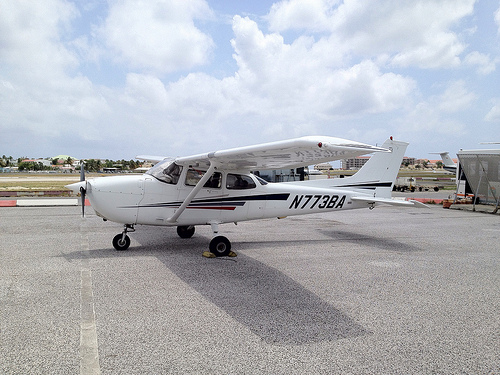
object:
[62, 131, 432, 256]
plane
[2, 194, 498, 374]
ground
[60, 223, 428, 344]
shadow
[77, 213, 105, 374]
line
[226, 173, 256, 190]
window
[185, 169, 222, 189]
window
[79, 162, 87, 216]
propeller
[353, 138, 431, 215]
tail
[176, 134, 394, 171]
wing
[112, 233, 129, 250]
tire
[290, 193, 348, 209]
writing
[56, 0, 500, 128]
sky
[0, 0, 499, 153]
clouds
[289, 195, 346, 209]
number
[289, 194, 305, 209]
letter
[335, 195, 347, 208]
letter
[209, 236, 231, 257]
tire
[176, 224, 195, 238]
tire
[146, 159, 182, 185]
cockpit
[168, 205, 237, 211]
stripe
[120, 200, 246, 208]
stripe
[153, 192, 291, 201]
stripe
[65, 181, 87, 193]
nosecone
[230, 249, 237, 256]
chock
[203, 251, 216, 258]
chock